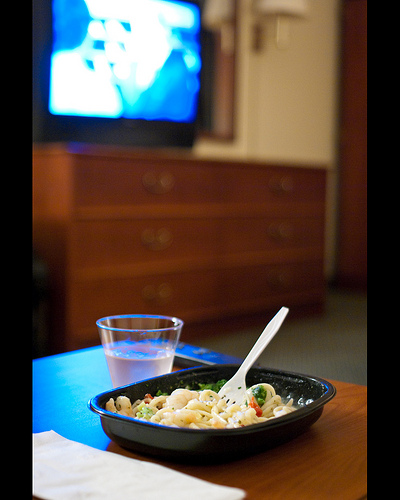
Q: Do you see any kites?
A: No, there are no kites.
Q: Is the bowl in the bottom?
A: Yes, the bowl is in the bottom of the image.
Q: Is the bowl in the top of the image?
A: No, the bowl is in the bottom of the image.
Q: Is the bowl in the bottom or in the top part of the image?
A: The bowl is in the bottom of the image.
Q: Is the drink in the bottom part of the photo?
A: Yes, the drink is in the bottom of the image.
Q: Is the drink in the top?
A: No, the drink is in the bottom of the image.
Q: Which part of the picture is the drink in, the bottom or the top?
A: The drink is in the bottom of the image.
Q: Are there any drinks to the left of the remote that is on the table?
A: Yes, there is a drink to the left of the remote.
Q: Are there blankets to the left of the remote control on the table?
A: No, there is a drink to the left of the remote.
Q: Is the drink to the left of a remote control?
A: Yes, the drink is to the left of a remote control.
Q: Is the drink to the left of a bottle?
A: No, the drink is to the left of a remote control.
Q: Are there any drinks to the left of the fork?
A: Yes, there is a drink to the left of the fork.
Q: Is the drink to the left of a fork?
A: Yes, the drink is to the left of a fork.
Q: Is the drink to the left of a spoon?
A: No, the drink is to the left of a fork.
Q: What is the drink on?
A: The drink is on the table.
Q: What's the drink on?
A: The drink is on the table.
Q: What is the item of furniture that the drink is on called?
A: The piece of furniture is a table.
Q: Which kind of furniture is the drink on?
A: The drink is on the table.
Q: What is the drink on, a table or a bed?
A: The drink is on a table.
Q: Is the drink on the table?
A: Yes, the drink is on the table.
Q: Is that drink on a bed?
A: No, the drink is on the table.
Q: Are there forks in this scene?
A: Yes, there is a fork.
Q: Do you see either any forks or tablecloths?
A: Yes, there is a fork.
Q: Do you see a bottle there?
A: No, there are no bottles.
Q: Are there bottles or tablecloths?
A: No, there are no bottles or tablecloths.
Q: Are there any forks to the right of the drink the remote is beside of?
A: Yes, there is a fork to the right of the drink.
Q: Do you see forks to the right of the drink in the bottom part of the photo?
A: Yes, there is a fork to the right of the drink.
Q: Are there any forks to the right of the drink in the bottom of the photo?
A: Yes, there is a fork to the right of the drink.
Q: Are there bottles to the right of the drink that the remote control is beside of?
A: No, there is a fork to the right of the drink.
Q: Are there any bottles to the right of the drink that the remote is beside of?
A: No, there is a fork to the right of the drink.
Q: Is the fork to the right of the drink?
A: Yes, the fork is to the right of the drink.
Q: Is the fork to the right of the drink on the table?
A: Yes, the fork is to the right of the drink.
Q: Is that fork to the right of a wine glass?
A: No, the fork is to the right of the drink.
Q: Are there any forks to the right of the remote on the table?
A: Yes, there is a fork to the right of the remote control.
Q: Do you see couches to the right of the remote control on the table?
A: No, there is a fork to the right of the remote control.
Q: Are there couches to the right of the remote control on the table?
A: No, there is a fork to the right of the remote control.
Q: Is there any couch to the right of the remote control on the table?
A: No, there is a fork to the right of the remote control.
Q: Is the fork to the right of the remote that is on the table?
A: Yes, the fork is to the right of the remote.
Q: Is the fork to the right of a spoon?
A: No, the fork is to the right of the remote.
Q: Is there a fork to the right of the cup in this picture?
A: Yes, there is a fork to the right of the cup.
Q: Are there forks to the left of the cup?
A: No, the fork is to the right of the cup.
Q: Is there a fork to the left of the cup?
A: No, the fork is to the right of the cup.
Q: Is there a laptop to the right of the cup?
A: No, there is a fork to the right of the cup.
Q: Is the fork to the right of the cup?
A: Yes, the fork is to the right of the cup.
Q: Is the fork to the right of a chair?
A: No, the fork is to the right of the cup.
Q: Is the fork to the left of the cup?
A: No, the fork is to the right of the cup.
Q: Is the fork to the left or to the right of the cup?
A: The fork is to the right of the cup.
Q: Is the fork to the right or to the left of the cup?
A: The fork is to the right of the cup.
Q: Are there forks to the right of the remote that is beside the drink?
A: Yes, there is a fork to the right of the remote.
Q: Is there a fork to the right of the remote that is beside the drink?
A: Yes, there is a fork to the right of the remote.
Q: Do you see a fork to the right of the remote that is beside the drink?
A: Yes, there is a fork to the right of the remote.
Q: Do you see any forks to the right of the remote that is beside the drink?
A: Yes, there is a fork to the right of the remote.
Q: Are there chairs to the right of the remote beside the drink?
A: No, there is a fork to the right of the remote control.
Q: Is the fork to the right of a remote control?
A: Yes, the fork is to the right of a remote control.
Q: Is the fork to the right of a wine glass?
A: No, the fork is to the right of a remote control.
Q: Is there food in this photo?
A: Yes, there is food.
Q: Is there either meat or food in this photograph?
A: Yes, there is food.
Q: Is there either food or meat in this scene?
A: Yes, there is food.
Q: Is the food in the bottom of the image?
A: Yes, the food is in the bottom of the image.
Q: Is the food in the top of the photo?
A: No, the food is in the bottom of the image.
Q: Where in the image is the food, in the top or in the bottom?
A: The food is in the bottom of the image.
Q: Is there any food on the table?
A: Yes, there is food on the table.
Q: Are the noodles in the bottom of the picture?
A: Yes, the noodles are in the bottom of the image.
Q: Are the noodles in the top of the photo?
A: No, the noodles are in the bottom of the image.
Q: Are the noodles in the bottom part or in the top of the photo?
A: The noodles are in the bottom of the image.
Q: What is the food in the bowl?
A: The food is noodles.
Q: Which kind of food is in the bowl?
A: The food is noodles.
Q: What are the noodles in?
A: The noodles are in the bowl.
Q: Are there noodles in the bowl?
A: Yes, there are noodles in the bowl.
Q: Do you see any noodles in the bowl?
A: Yes, there are noodles in the bowl.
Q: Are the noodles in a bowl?
A: Yes, the noodles are in a bowl.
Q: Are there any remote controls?
A: Yes, there is a remote control.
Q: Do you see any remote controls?
A: Yes, there is a remote control.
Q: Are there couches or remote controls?
A: Yes, there is a remote control.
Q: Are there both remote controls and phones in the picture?
A: No, there is a remote control but no phones.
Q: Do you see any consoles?
A: No, there are no consoles.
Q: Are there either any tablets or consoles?
A: No, there are no consoles or tablets.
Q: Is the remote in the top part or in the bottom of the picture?
A: The remote is in the bottom of the image.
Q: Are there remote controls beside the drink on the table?
A: Yes, there is a remote control beside the drink.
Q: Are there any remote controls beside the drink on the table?
A: Yes, there is a remote control beside the drink.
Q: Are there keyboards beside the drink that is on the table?
A: No, there is a remote control beside the drink.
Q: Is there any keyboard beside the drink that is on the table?
A: No, there is a remote control beside the drink.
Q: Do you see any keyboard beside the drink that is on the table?
A: No, there is a remote control beside the drink.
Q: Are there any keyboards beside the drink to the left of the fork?
A: No, there is a remote control beside the drink.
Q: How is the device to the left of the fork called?
A: The device is a remote control.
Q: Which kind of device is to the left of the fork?
A: The device is a remote control.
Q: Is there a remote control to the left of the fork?
A: Yes, there is a remote control to the left of the fork.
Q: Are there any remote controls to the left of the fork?
A: Yes, there is a remote control to the left of the fork.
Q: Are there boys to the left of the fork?
A: No, there is a remote control to the left of the fork.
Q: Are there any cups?
A: Yes, there is a cup.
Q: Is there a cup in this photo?
A: Yes, there is a cup.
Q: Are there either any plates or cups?
A: Yes, there is a cup.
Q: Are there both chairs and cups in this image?
A: No, there is a cup but no chairs.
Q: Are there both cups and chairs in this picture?
A: No, there is a cup but no chairs.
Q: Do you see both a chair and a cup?
A: No, there is a cup but no chairs.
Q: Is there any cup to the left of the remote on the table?
A: Yes, there is a cup to the left of the remote.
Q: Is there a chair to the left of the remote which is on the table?
A: No, there is a cup to the left of the remote.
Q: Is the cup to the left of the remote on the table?
A: Yes, the cup is to the left of the remote.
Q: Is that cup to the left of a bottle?
A: No, the cup is to the left of the remote.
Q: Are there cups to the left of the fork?
A: Yes, there is a cup to the left of the fork.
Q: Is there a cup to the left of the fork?
A: Yes, there is a cup to the left of the fork.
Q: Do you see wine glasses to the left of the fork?
A: No, there is a cup to the left of the fork.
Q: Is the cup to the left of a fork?
A: Yes, the cup is to the left of a fork.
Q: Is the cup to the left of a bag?
A: No, the cup is to the left of a fork.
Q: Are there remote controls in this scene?
A: Yes, there is a remote control.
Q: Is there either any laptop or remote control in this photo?
A: Yes, there is a remote control.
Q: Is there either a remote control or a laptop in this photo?
A: Yes, there is a remote control.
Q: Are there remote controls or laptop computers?
A: Yes, there is a remote control.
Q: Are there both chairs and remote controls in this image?
A: No, there is a remote control but no chairs.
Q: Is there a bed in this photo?
A: No, there are no beds.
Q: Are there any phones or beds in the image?
A: No, there are no beds or phones.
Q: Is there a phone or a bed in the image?
A: No, there are no beds or phones.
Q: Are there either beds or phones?
A: No, there are no beds or phones.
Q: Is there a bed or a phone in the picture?
A: No, there are no beds or phones.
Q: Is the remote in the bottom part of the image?
A: Yes, the remote is in the bottom of the image.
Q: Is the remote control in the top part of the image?
A: No, the remote control is in the bottom of the image.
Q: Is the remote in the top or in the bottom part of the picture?
A: The remote is in the bottom of the image.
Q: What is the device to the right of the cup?
A: The device is a remote control.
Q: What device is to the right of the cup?
A: The device is a remote control.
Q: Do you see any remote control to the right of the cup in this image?
A: Yes, there is a remote control to the right of the cup.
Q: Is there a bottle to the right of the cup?
A: No, there is a remote control to the right of the cup.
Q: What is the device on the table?
A: The device is a remote control.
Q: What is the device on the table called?
A: The device is a remote control.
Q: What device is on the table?
A: The device is a remote control.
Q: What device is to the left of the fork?
A: The device is a remote control.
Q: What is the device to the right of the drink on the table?
A: The device is a remote control.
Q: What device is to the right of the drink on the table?
A: The device is a remote control.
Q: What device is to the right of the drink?
A: The device is a remote control.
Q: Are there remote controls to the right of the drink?
A: Yes, there is a remote control to the right of the drink.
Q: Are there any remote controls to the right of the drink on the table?
A: Yes, there is a remote control to the right of the drink.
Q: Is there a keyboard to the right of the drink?
A: No, there is a remote control to the right of the drink.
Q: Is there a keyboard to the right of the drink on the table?
A: No, there is a remote control to the right of the drink.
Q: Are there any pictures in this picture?
A: No, there are no pictures.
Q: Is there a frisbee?
A: No, there are no frisbees.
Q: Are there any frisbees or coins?
A: No, there are no frisbees or coins.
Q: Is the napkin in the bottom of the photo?
A: Yes, the napkin is in the bottom of the image.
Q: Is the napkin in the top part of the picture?
A: No, the napkin is in the bottom of the image.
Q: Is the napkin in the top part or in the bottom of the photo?
A: The napkin is in the bottom of the image.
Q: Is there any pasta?
A: Yes, there is pasta.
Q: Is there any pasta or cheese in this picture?
A: Yes, there is pasta.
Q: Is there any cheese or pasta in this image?
A: Yes, there is pasta.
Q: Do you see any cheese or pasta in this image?
A: Yes, there is pasta.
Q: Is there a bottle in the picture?
A: No, there are no bottles.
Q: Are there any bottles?
A: No, there are no bottles.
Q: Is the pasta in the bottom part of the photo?
A: Yes, the pasta is in the bottom of the image.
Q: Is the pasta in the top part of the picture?
A: No, the pasta is in the bottom of the image.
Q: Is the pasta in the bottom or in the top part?
A: The pasta is in the bottom of the image.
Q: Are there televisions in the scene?
A: Yes, there is a television.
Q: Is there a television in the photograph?
A: Yes, there is a television.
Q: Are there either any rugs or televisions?
A: Yes, there is a television.